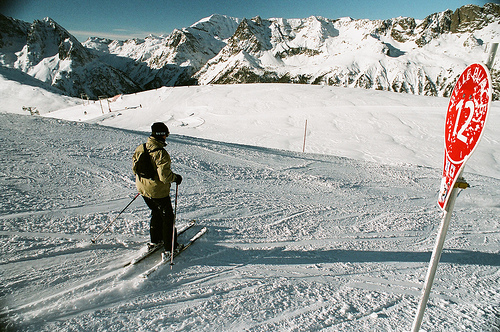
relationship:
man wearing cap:
[128, 117, 185, 265] [149, 120, 171, 139]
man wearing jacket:
[128, 117, 185, 265] [131, 139, 179, 202]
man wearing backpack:
[128, 117, 185, 265] [134, 142, 166, 184]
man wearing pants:
[128, 117, 185, 265] [136, 195, 184, 259]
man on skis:
[128, 117, 185, 265] [132, 217, 210, 282]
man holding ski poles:
[128, 117, 185, 265] [167, 176, 186, 271]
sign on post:
[437, 63, 494, 214] [408, 39, 499, 331]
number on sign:
[450, 98, 476, 148] [437, 63, 494, 214]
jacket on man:
[131, 139, 179, 202] [128, 117, 185, 265]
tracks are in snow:
[8, 134, 495, 325] [2, 77, 499, 330]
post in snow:
[408, 39, 499, 331] [8, 134, 495, 325]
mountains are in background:
[1, 5, 499, 96] [1, 1, 499, 115]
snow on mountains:
[7, 14, 488, 82] [1, 5, 499, 96]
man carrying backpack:
[128, 117, 185, 265] [134, 142, 166, 184]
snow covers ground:
[2, 77, 499, 330] [8, 116, 496, 332]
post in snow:
[408, 39, 499, 331] [2, 77, 499, 330]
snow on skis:
[130, 245, 171, 273] [132, 217, 210, 282]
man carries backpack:
[128, 117, 185, 265] [134, 142, 166, 184]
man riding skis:
[128, 117, 185, 265] [132, 217, 210, 282]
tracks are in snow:
[8, 134, 495, 325] [0, 15, 498, 329]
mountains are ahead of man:
[1, 5, 499, 96] [128, 117, 185, 265]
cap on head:
[149, 120, 171, 139] [151, 120, 171, 147]